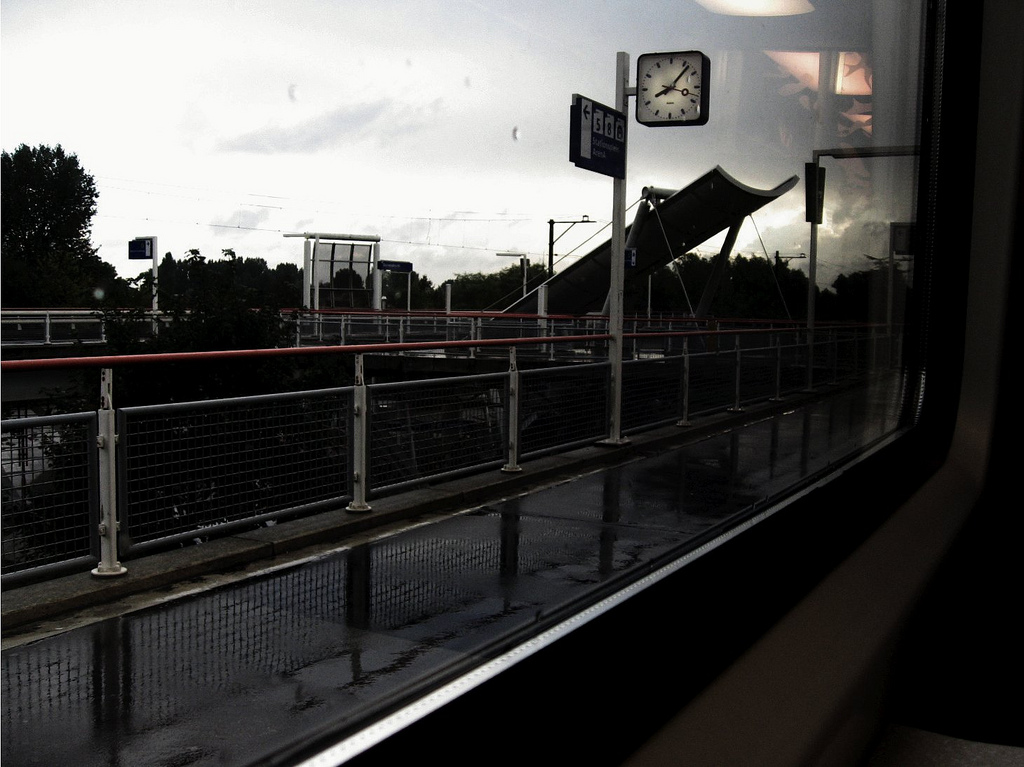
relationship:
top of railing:
[5, 329, 615, 366] [1, 332, 827, 371]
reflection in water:
[1, 471, 682, 763] [70, 512, 680, 727]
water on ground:
[70, 512, 680, 727] [7, 386, 1020, 753]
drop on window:
[506, 117, 526, 140] [8, 1, 945, 764]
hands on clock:
[653, 68, 688, 103] [637, 51, 707, 124]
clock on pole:
[629, 50, 707, 127] [607, 40, 633, 559]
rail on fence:
[65, 379, 361, 414] [124, 384, 350, 530]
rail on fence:
[262, 467, 585, 558] [365, 501, 511, 619]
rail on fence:
[501, 463, 638, 513] [497, 454, 615, 590]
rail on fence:
[491, 350, 630, 387] [517, 344, 610, 452]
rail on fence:
[711, 402, 779, 441] [716, 412, 775, 492]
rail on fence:
[618, 344, 686, 373] [620, 340, 681, 433]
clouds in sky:
[208, 96, 433, 159] [261, 77, 420, 166]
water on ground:
[69, 512, 679, 727] [208, 579, 297, 713]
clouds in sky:
[208, 96, 436, 154] [60, 61, 536, 310]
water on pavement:
[69, 512, 679, 727] [238, 400, 345, 750]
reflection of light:
[694, 3, 875, 143] [701, 0, 813, 21]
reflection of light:
[694, 3, 875, 143] [837, 103, 876, 139]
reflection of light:
[694, 3, 875, 143] [764, 49, 872, 98]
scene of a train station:
[62, 36, 860, 562] [5, 156, 917, 762]